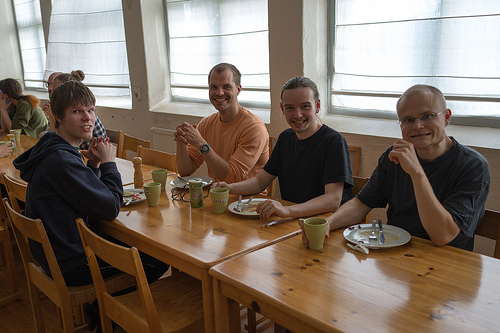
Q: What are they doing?
A: Smiling.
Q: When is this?
A: Daytime.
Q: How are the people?
A: Happy.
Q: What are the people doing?
A: Posing.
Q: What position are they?
A: Seated.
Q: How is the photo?
A: Clear.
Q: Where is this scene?
A: At a restaurant.